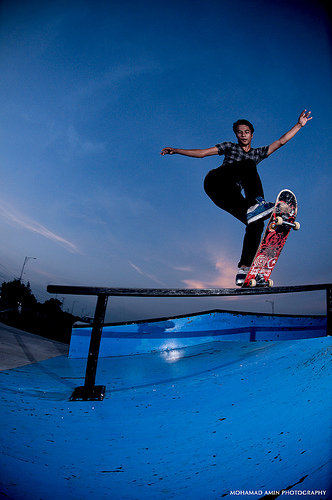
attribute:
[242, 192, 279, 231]
sneaker — blue, white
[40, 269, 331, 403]
railing — black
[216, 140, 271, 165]
top — squared, black, gray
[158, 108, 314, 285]
skateboard — red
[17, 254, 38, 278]
pole — steep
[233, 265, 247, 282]
shoe — gym, blue and white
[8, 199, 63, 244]
clouds — white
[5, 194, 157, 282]
clouds — white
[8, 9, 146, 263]
sky — blue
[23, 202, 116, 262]
clouds — whispy, white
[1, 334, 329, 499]
ramp — blue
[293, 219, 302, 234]
wheel — white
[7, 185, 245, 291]
clouds — white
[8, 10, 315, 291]
sky — blue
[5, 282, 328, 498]
ramp — black, for skating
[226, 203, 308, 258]
shoes — blue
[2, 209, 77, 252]
cloud — white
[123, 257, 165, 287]
cloud — white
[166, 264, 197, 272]
cloud — white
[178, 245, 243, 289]
cloud — white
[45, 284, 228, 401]
seat — metal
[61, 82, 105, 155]
cloud — white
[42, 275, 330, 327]
rail — black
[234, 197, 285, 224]
shoe — blue and white, gym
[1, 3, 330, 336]
sky — blue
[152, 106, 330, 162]
arms — extended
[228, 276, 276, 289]
sole — white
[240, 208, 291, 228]
sole — white